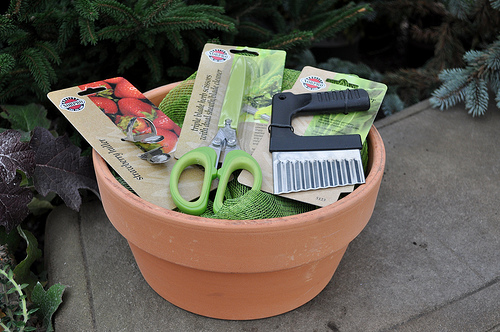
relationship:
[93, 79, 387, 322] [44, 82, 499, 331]
planter on bench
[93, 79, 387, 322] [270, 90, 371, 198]
planter has tool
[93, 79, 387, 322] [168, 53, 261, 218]
planter has tool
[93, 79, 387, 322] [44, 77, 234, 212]
planter has tool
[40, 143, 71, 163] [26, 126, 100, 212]
line on leaf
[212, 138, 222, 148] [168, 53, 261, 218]
screw on shears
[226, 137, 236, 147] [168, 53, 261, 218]
screw on shears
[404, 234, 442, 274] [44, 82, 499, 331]
spot on bench